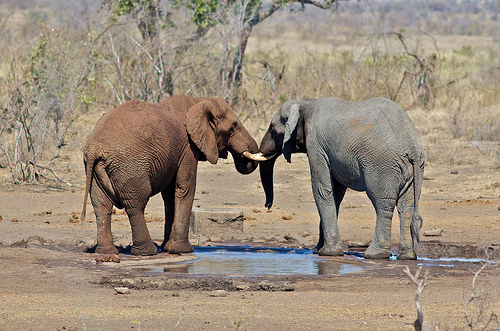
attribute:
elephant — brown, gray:
[228, 94, 449, 273]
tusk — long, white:
[242, 148, 276, 163]